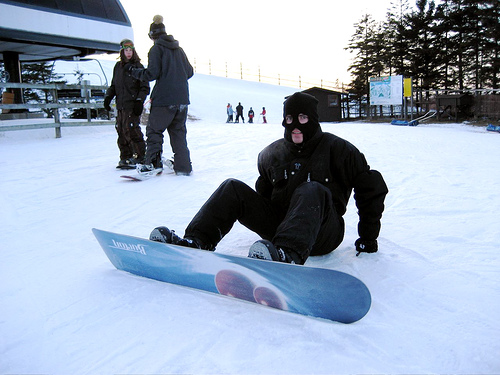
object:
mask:
[279, 91, 321, 144]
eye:
[296, 112, 308, 122]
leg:
[113, 108, 132, 161]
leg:
[126, 109, 146, 161]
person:
[103, 39, 150, 165]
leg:
[145, 104, 172, 165]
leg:
[167, 112, 192, 173]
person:
[121, 14, 197, 178]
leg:
[183, 176, 281, 250]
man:
[146, 91, 386, 265]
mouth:
[289, 129, 305, 139]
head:
[280, 94, 319, 144]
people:
[233, 101, 247, 124]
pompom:
[152, 14, 163, 24]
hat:
[146, 13, 163, 39]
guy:
[132, 17, 194, 174]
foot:
[246, 235, 283, 267]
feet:
[144, 226, 217, 250]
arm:
[352, 158, 389, 238]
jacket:
[256, 135, 385, 240]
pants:
[180, 179, 344, 266]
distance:
[1, 0, 498, 93]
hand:
[353, 235, 381, 253]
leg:
[268, 183, 344, 259]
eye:
[284, 113, 293, 125]